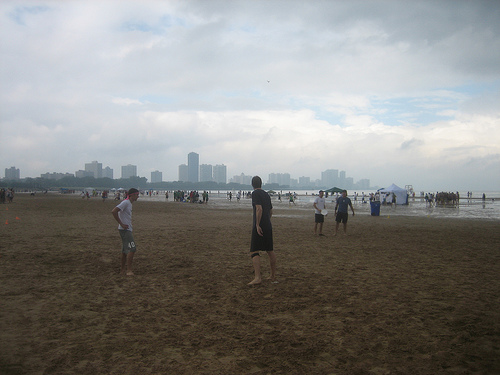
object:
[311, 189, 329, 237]
man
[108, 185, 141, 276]
man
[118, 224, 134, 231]
waist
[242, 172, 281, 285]
man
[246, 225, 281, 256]
shorts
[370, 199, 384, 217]
bin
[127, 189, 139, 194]
ribbon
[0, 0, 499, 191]
sky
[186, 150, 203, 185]
building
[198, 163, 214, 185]
building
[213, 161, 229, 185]
building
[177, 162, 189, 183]
building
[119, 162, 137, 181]
building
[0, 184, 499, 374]
beach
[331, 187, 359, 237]
person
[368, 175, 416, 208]
tent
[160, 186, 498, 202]
water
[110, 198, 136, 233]
shirt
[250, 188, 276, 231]
shirt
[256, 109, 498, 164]
cloud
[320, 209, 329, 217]
frisbee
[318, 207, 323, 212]
hand